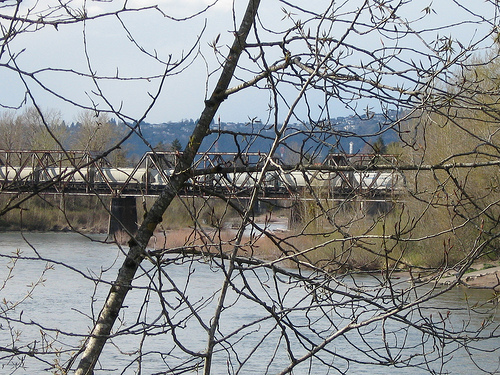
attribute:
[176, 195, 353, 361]
branches — barren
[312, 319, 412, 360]
water — calm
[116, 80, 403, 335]
branches — barren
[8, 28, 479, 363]
branches — tree, bunch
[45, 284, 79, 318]
water — calm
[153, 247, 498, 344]
branch — barren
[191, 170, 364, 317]
branch — barren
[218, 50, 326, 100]
branch — barren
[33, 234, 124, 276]
water — calm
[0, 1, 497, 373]
branches — bunch, tree, barren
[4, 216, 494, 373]
water — body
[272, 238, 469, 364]
branch —  barren tree ,  without leaves